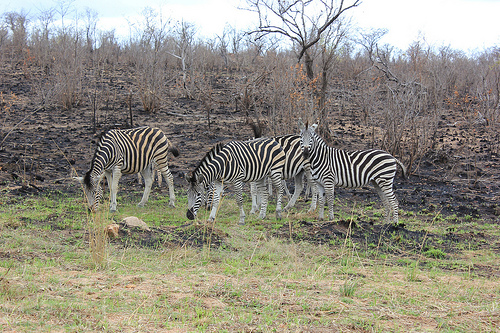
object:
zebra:
[73, 126, 180, 213]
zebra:
[185, 137, 286, 226]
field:
[1, 180, 500, 333]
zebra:
[296, 122, 407, 225]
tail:
[394, 157, 408, 180]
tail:
[167, 137, 181, 159]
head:
[183, 170, 205, 220]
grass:
[1, 191, 403, 332]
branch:
[243, 29, 301, 45]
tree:
[234, 0, 361, 115]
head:
[78, 173, 106, 213]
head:
[297, 120, 321, 159]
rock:
[120, 216, 149, 228]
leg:
[156, 155, 177, 207]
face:
[299, 132, 313, 157]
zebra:
[269, 134, 319, 216]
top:
[236, 0, 358, 44]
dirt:
[108, 220, 230, 247]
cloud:
[94, 16, 139, 26]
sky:
[0, 1, 499, 60]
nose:
[186, 209, 196, 220]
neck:
[86, 138, 110, 177]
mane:
[82, 131, 111, 185]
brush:
[370, 121, 427, 148]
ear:
[308, 121, 319, 131]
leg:
[313, 175, 335, 221]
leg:
[372, 175, 399, 225]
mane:
[192, 142, 234, 184]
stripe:
[341, 150, 389, 176]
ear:
[297, 121, 306, 132]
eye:
[310, 135, 315, 141]